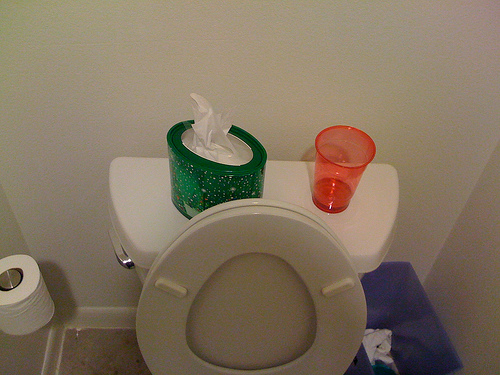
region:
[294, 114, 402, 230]
Translucent red plastic cup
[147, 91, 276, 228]
Green tissue paper dispenser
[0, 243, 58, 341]
White roll of toilet paper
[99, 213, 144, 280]
Silver metal toilet lever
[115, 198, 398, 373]
White plastic toilet seat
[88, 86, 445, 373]
Toilet with things sitting on top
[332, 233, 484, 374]
Blue plastic waste basket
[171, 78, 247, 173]
Small white tissue paper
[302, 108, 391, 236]
Medium sized plastic cup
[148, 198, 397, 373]
Elongated white toilet seat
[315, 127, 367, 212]
Empty red plastic cup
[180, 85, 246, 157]
White tissue paper in dispenser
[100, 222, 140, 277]
Chrome toilet flush handle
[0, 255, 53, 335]
Toilet paper and paper dispenser.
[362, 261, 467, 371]
Purple colored trash bin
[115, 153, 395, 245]
Tan colored toilet tank lid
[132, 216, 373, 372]
Tan colored toilet seat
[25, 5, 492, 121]
Tan colored painted walls.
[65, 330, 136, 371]
Tan colored tile floor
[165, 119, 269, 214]
Green toilet tissue dispenser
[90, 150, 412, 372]
a white toilet with the seat up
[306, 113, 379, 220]
a red clear cup sitting on the back of toilet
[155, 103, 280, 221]
a green with white spots tissue holder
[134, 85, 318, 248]
tissue holder sitting on the back of the toilet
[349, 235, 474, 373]
a clear blue trash can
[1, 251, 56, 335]
a roll of toilet paper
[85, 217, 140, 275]
handle to flush the toilet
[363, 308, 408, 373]
trash in the garbage can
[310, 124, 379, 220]
an empty plastic cup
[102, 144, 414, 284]
tank of a toilet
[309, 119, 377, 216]
A red plastic cup on the back of a toilet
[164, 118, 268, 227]
a green decorative tissue box cover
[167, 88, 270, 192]
A box of facial tissues on the back of a toilet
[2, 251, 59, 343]
Toilet paper roll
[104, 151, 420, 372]
A toilet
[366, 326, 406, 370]
Trash in a trashcan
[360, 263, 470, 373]
Trashcan next to a toilet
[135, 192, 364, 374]
The underside of a raised toilet seat and lid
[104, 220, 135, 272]
A toilet flush lever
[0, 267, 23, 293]
Part of a silver toilet paper roll holder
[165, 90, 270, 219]
Green tissue holder on toilet tank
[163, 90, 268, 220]
White tissue in green holder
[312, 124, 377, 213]
Red plastic cup on top of toilet tank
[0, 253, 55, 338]
Tissue paper on the roll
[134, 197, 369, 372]
Toilet seat and cover raised up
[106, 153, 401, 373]
White toilet in the bathroom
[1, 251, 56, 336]
Tissue paper in the restroom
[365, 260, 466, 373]
Blue trash can beside the toilet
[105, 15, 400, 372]
White wall behind the toilet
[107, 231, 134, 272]
Silver flush handle on the toilet